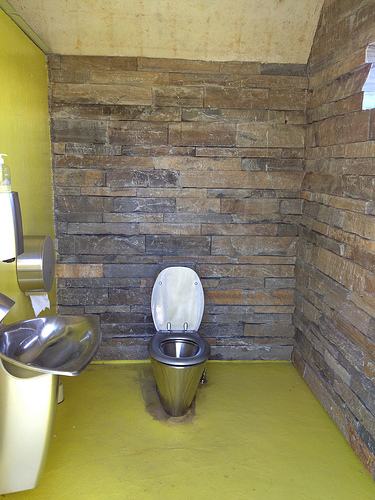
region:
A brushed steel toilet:
[146, 266, 209, 414]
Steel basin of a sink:
[0, 311, 103, 376]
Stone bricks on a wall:
[58, 65, 303, 264]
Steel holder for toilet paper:
[17, 232, 58, 317]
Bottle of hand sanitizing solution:
[0, 151, 14, 190]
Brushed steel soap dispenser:
[2, 189, 26, 264]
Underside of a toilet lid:
[149, 264, 202, 333]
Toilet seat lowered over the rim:
[147, 330, 211, 365]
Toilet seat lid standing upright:
[150, 265, 205, 335]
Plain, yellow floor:
[204, 397, 322, 480]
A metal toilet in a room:
[144, 266, 209, 416]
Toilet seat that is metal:
[147, 329, 207, 365]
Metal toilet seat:
[147, 329, 210, 364]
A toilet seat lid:
[147, 266, 205, 332]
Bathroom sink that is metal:
[4, 314, 102, 375]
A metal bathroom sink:
[2, 311, 103, 378]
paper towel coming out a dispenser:
[28, 293, 51, 315]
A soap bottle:
[0, 151, 16, 193]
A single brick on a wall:
[56, 263, 103, 276]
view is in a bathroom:
[92, 239, 290, 485]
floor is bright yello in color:
[235, 408, 307, 499]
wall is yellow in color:
[4, 57, 71, 154]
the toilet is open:
[145, 325, 225, 397]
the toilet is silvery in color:
[140, 294, 212, 408]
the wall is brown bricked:
[315, 224, 369, 379]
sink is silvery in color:
[6, 305, 107, 372]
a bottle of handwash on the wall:
[1, 156, 23, 192]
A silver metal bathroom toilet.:
[150, 267, 210, 417]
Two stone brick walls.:
[45, 0, 372, 475]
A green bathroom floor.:
[0, 356, 372, 494]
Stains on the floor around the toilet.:
[132, 360, 210, 421]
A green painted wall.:
[0, 1, 54, 332]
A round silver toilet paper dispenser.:
[15, 235, 52, 290]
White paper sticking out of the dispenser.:
[15, 233, 52, 314]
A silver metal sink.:
[0, 312, 101, 377]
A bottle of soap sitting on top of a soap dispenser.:
[0, 151, 22, 262]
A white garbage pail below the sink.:
[0, 357, 56, 492]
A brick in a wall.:
[103, 165, 149, 188]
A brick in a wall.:
[145, 233, 213, 257]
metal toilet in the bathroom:
[145, 267, 215, 420]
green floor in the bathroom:
[30, 351, 367, 496]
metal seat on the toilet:
[150, 330, 205, 365]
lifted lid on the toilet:
[150, 263, 204, 326]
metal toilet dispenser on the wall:
[16, 231, 59, 291]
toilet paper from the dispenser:
[25, 292, 49, 317]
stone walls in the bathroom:
[51, 73, 374, 452]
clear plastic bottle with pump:
[0, 149, 11, 185]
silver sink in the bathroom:
[0, 309, 101, 378]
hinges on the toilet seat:
[166, 320, 189, 329]